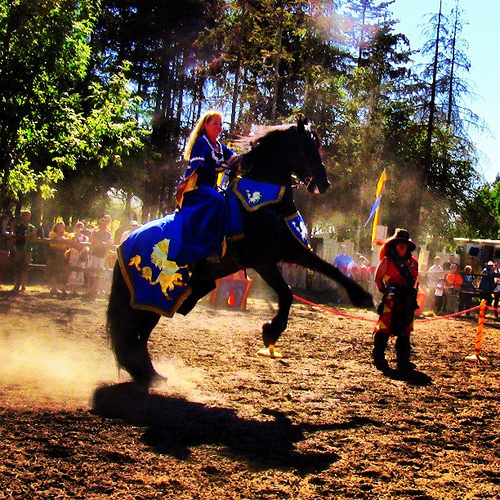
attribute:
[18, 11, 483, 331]
trees — tall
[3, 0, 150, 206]
leaves — green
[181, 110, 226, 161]
hair — woman's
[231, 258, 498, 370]
rope — red, safety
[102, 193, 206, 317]
cloth — blue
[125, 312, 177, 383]
leg — back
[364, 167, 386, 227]
flag — yellow, blue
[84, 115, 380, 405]
horse — black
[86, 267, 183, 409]
legs — hind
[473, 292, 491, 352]
pole — red, yellow